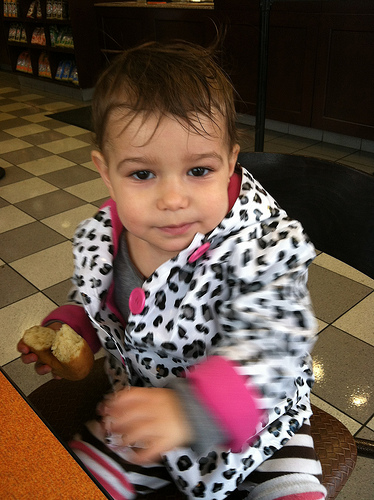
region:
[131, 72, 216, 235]
the face of a child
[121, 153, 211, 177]
the eyes of a child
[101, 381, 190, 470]
the hand of a child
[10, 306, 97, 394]
a hand holding bagel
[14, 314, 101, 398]
a hand holding a half eaten bagel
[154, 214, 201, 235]
the mouth of a child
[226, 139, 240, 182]
the ear of a child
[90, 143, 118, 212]
the ear of a child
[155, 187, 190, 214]
the nose of a child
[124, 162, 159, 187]
the eye of a child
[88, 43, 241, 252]
Toddler is not smiling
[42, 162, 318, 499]
Leopard print toddler jacket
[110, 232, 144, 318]
Grey shirt under jacket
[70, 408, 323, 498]
Black, pink and white striped leggings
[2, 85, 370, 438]
Tile floor with different shades of grey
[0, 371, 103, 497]
Brown table with black trim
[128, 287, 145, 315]
Pink button on jacket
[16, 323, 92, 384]
Partially eaten donut in hand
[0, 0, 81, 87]
Snack foods on display in back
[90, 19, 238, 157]
Messy hair on toddler's head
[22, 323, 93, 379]
A donut bitten into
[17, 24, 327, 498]
A toddler eating a donut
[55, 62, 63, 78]
Bag of chips that is blue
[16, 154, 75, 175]
A white tile on the ground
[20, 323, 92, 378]
A plain brown donut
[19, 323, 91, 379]
A regular type of donut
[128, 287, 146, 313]
Pink button on a jacket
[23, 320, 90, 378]
A donut being eaten by a toddler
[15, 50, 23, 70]
A bag of chips on a rack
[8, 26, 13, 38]
A bag of chips sitting next to other ones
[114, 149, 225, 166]
Two brown eyebrows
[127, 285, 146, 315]
A pink button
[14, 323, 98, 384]
A partially eaten donut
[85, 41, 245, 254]
A toddler with brown hair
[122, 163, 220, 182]
A toddler's brown eyes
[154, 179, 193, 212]
A toddler's nose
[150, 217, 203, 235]
A toddler's mouth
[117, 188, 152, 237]
A toddler's cheek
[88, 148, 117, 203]
A toddler's right ear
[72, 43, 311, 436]
A toddler wearing an animal print jacket with pink trim